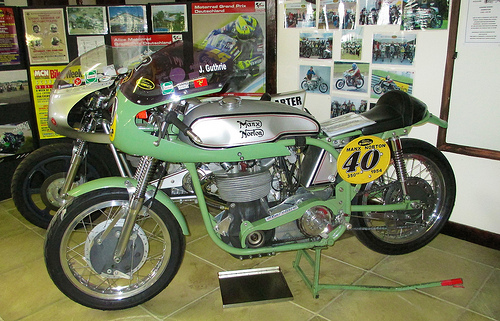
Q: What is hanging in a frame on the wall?
A: Pictures.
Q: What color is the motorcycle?
A: Green.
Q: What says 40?
A: Motorcycle sign.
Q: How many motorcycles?
A: Two.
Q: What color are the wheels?
A: Black.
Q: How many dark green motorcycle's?
A: One.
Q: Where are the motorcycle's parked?
A: In a room.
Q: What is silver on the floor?
A: Metal pan.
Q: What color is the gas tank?
A: Silver.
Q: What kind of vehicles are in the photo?
A: Motorcycles.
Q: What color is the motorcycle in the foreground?
A: Green.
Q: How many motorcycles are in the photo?
A: Two.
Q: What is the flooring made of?
A: Tiles.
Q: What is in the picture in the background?
A: People on motorcycles.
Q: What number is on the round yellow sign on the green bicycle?
A: 40.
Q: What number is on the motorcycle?
A: 40.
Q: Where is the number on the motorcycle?
A: Side.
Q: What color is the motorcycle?
A: Green.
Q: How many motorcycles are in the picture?
A: Two.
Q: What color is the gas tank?
A: Silver.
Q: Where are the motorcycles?
A: Inside building.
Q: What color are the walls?
A: White.